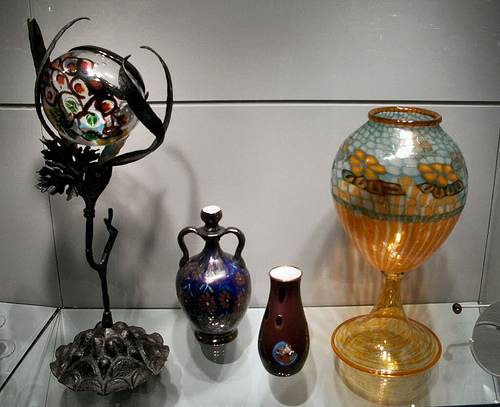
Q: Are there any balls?
A: Yes, there is a ball.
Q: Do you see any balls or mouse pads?
A: Yes, there is a ball.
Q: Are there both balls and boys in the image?
A: No, there is a ball but no boys.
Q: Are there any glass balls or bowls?
A: Yes, there is a glass ball.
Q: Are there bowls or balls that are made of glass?
A: Yes, the ball is made of glass.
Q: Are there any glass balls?
A: Yes, there is a ball that is made of glass.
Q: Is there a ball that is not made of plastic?
A: Yes, there is a ball that is made of glass.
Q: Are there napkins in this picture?
A: No, there are no napkins.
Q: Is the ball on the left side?
A: Yes, the ball is on the left of the image.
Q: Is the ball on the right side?
A: No, the ball is on the left of the image.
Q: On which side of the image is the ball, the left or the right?
A: The ball is on the left of the image.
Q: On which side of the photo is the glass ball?
A: The ball is on the left of the image.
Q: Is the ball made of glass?
A: Yes, the ball is made of glass.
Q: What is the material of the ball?
A: The ball is made of glass.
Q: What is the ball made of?
A: The ball is made of glass.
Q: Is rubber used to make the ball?
A: No, the ball is made of glass.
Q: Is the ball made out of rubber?
A: No, the ball is made of glass.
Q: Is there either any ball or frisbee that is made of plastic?
A: No, there is a ball but it is made of glass.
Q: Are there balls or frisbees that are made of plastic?
A: No, there is a ball but it is made of glass.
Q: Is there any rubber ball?
A: No, there is a ball but it is made of glass.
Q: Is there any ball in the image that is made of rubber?
A: No, there is a ball but it is made of glass.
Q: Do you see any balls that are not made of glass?
A: No, there is a ball but it is made of glass.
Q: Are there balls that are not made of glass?
A: No, there is a ball but it is made of glass.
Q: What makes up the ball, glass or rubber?
A: The ball is made of glass.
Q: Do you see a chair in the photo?
A: No, there are no chairs.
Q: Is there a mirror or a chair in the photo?
A: No, there are no chairs or mirrors.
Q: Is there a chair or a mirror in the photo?
A: No, there are no chairs or mirrors.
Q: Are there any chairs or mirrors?
A: No, there are no chairs or mirrors.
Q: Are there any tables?
A: Yes, there is a table.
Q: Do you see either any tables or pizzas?
A: Yes, there is a table.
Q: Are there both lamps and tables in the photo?
A: No, there is a table but no lamps.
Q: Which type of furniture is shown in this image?
A: The furniture is a table.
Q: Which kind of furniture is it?
A: The piece of furniture is a table.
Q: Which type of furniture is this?
A: That is a table.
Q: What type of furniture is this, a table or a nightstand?
A: That is a table.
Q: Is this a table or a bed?
A: This is a table.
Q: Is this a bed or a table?
A: This is a table.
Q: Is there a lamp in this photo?
A: No, there are no lamps.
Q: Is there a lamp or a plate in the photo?
A: No, there are no lamps or plates.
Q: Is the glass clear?
A: Yes, the glass is clear.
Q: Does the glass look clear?
A: Yes, the glass is clear.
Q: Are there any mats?
A: No, there are no mats.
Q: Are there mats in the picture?
A: No, there are no mats.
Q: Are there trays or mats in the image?
A: No, there are no mats or trays.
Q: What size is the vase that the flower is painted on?
A: The vase is small.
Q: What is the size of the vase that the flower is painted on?
A: The vase is small.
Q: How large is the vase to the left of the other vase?
A: The vase is small.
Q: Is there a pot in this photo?
A: No, there are no pots.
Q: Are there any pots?
A: No, there are no pots.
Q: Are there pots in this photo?
A: No, there are no pots.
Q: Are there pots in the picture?
A: No, there are no pots.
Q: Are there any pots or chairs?
A: No, there are no pots or chairs.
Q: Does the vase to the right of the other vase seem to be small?
A: Yes, the vase is small.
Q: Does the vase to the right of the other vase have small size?
A: Yes, the vase is small.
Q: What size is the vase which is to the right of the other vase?
A: The vase is small.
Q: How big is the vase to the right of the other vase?
A: The vase is small.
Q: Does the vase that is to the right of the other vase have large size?
A: No, the vase is small.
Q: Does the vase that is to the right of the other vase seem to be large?
A: No, the vase is small.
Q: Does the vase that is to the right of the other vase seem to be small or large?
A: The vase is small.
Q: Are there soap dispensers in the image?
A: No, there are no soap dispensers.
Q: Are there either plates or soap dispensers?
A: No, there are no soap dispensers or plates.